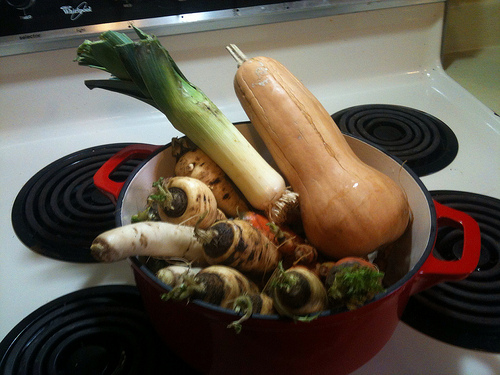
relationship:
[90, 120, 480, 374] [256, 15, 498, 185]
pot on stove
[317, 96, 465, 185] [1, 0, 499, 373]
burner on stove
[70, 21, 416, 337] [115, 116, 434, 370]
vegetable in pot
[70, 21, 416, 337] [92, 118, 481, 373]
vegetable in pot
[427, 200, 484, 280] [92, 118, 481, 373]
handle in pot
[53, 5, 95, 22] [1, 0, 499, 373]
logo on stove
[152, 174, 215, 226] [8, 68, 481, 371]
vegetable in stove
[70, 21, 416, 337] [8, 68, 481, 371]
vegetable in stove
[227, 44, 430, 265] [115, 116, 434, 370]
squash in pot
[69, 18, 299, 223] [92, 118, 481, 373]
leek in pot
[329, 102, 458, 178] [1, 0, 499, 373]
burner on stove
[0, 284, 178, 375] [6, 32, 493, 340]
burner on stove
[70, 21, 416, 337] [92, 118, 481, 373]
vegetable on pot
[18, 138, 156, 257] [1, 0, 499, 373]
burner on stove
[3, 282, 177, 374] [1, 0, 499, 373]
burner on stove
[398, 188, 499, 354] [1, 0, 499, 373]
burner on stove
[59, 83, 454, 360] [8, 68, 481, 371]
pot on stove